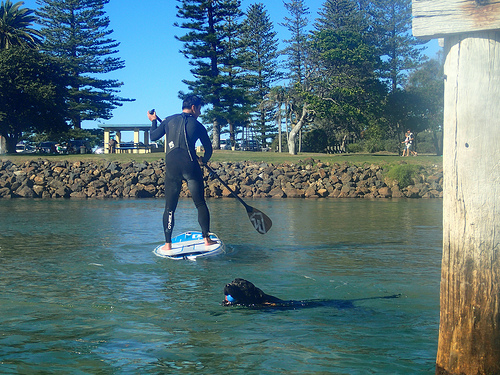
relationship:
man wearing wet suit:
[147, 95, 217, 250] [155, 114, 214, 240]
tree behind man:
[172, 3, 245, 148] [147, 95, 217, 250]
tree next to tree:
[172, 3, 245, 148] [221, 0, 248, 151]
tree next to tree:
[221, 0, 248, 151] [237, 4, 280, 150]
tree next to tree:
[237, 4, 280, 150] [221, 0, 248, 151]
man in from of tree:
[148, 91, 219, 250] [172, 3, 245, 148]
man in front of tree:
[148, 91, 219, 250] [221, 0, 248, 151]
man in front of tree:
[148, 91, 219, 250] [237, 4, 280, 150]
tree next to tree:
[281, 2, 312, 154] [384, 86, 441, 155]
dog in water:
[223, 275, 404, 323] [1, 196, 443, 373]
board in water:
[155, 228, 224, 263] [1, 196, 443, 373]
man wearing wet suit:
[148, 91, 219, 250] [155, 114, 214, 240]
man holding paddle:
[148, 91, 219, 250] [147, 109, 273, 237]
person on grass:
[404, 131, 414, 154] [4, 147, 443, 170]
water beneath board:
[1, 196, 443, 373] [155, 228, 224, 263]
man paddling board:
[148, 91, 219, 250] [155, 228, 224, 263]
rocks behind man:
[1, 159, 440, 199] [148, 91, 219, 250]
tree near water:
[1, 42, 75, 154] [1, 196, 443, 373]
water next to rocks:
[1, 196, 443, 373] [1, 159, 440, 199]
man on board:
[148, 91, 219, 250] [155, 228, 224, 263]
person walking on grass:
[404, 131, 414, 154] [4, 147, 443, 170]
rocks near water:
[1, 159, 440, 199] [1, 196, 443, 373]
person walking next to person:
[404, 131, 414, 154] [399, 130, 407, 154]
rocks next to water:
[1, 159, 440, 199] [1, 196, 443, 373]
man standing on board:
[148, 91, 219, 250] [152, 230, 225, 261]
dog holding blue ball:
[223, 275, 404, 323] [223, 290, 237, 304]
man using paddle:
[148, 91, 219, 250] [147, 109, 273, 237]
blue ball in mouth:
[223, 290, 237, 304] [217, 288, 242, 311]